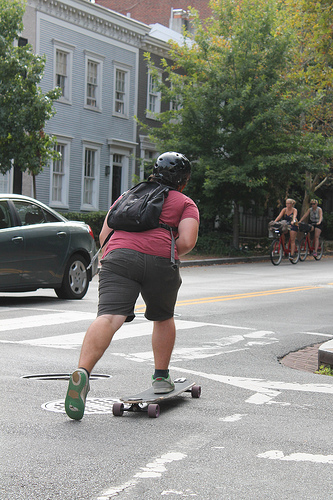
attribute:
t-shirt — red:
[101, 185, 199, 259]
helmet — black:
[139, 148, 200, 188]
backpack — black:
[107, 184, 161, 230]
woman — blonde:
[273, 197, 299, 255]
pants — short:
[98, 247, 180, 324]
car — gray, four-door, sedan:
[1, 191, 108, 299]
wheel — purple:
[111, 402, 122, 415]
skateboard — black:
[119, 357, 232, 430]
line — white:
[22, 316, 206, 348]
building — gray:
[0, 0, 209, 216]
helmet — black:
[148, 144, 191, 186]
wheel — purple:
[183, 384, 208, 400]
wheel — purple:
[188, 383, 207, 402]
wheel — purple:
[143, 398, 161, 419]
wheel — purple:
[110, 401, 126, 421]